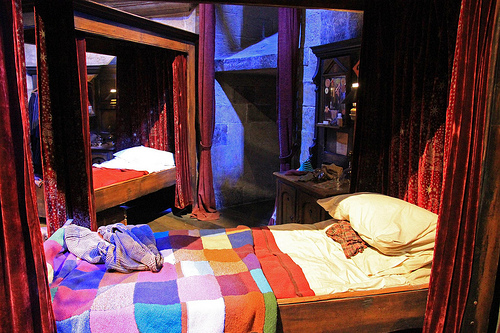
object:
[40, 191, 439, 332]
bed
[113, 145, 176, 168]
pillow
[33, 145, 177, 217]
bed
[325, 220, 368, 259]
cloth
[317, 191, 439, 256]
pillow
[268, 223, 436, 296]
sheet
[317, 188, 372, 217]
shadow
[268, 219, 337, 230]
shadow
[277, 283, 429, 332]
wood side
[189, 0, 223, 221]
drape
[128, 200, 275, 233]
floor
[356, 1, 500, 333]
drape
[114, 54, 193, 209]
drape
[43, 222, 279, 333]
bedspread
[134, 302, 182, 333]
square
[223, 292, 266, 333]
square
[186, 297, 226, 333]
square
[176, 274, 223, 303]
square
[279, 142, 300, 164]
band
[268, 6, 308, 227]
drape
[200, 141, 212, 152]
band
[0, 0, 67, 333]
curtain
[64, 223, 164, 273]
robe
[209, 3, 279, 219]
entrance way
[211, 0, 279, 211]
concrete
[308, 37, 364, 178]
hutch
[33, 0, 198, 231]
alcove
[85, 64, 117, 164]
cabinet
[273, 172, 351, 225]
nightstand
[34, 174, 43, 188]
pajamas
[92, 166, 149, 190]
blanket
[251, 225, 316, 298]
blanket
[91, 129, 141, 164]
table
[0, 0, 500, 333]
room